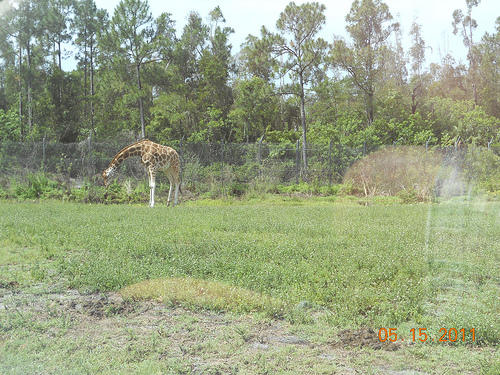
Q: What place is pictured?
A: It is a field.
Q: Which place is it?
A: It is a field.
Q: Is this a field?
A: Yes, it is a field.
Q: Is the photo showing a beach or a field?
A: It is showing a field.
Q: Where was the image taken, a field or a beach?
A: It was taken at a field.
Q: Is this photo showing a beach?
A: No, the picture is showing a field.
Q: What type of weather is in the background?
A: It is clear.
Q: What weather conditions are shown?
A: It is clear.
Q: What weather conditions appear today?
A: It is clear.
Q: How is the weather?
A: It is clear.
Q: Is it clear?
A: Yes, it is clear.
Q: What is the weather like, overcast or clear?
A: It is clear.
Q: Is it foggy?
A: No, it is clear.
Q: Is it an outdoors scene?
A: Yes, it is outdoors.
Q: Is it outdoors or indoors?
A: It is outdoors.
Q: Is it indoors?
A: No, it is outdoors.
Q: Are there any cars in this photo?
A: No, there are no cars.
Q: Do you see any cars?
A: No, there are no cars.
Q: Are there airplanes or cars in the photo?
A: No, there are no cars or airplanes.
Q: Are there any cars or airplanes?
A: No, there are no cars or airplanes.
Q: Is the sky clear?
A: Yes, the sky is clear.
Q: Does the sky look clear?
A: Yes, the sky is clear.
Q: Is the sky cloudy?
A: No, the sky is clear.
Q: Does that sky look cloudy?
A: No, the sky is clear.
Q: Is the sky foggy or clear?
A: The sky is clear.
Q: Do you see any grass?
A: Yes, there is grass.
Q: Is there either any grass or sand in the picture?
A: Yes, there is grass.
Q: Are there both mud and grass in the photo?
A: No, there is grass but no mud.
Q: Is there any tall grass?
A: Yes, there is tall grass.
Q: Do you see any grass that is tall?
A: Yes, there is grass that is tall.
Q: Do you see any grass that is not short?
A: Yes, there is tall grass.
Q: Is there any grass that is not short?
A: Yes, there is tall grass.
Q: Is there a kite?
A: No, there are no kites.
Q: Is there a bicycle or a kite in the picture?
A: No, there are no kites or bicycles.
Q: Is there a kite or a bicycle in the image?
A: No, there are no kites or bicycles.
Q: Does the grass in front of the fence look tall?
A: Yes, the grass is tall.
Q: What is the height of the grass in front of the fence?
A: The grass is tall.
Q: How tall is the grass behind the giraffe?
A: The grass is tall.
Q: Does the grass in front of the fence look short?
A: No, the grass is tall.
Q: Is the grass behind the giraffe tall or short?
A: The grass is tall.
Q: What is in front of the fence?
A: The grass is in front of the fence.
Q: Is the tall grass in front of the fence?
A: Yes, the grass is in front of the fence.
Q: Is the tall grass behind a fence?
A: No, the grass is in front of a fence.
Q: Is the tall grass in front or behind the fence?
A: The grass is in front of the fence.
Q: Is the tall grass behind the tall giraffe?
A: Yes, the grass is behind the giraffe.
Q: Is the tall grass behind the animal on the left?
A: Yes, the grass is behind the giraffe.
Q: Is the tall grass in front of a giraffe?
A: No, the grass is behind a giraffe.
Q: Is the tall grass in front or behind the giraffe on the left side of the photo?
A: The grass is behind the giraffe.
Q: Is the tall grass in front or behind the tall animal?
A: The grass is behind the giraffe.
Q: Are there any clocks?
A: No, there are no clocks.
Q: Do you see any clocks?
A: No, there are no clocks.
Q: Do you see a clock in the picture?
A: No, there are no clocks.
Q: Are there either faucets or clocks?
A: No, there are no clocks or faucets.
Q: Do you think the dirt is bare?
A: Yes, the dirt is bare.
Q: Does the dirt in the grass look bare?
A: Yes, the dirt is bare.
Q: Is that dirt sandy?
A: No, the dirt is bare.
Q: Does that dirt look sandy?
A: No, the dirt is bare.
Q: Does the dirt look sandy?
A: No, the dirt is bare.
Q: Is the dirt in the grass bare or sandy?
A: The dirt is bare.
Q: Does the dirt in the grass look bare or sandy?
A: The dirt is bare.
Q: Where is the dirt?
A: The dirt is in the grass.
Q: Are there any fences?
A: Yes, there is a fence.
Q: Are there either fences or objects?
A: Yes, there is a fence.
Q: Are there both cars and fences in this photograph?
A: No, there is a fence but no cars.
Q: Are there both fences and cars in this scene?
A: No, there is a fence but no cars.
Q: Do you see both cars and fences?
A: No, there is a fence but no cars.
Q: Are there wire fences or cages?
A: Yes, there is a wire fence.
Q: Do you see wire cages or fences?
A: Yes, there is a wire fence.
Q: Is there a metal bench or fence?
A: Yes, there is a metal fence.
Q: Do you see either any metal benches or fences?
A: Yes, there is a metal fence.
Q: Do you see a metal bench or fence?
A: Yes, there is a metal fence.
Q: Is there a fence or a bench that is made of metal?
A: Yes, the fence is made of metal.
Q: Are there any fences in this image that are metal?
A: Yes, there is a metal fence.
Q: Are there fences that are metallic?
A: Yes, there is a fence that is metallic.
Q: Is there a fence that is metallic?
A: Yes, there is a fence that is metallic.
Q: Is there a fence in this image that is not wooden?
A: Yes, there is a metallic fence.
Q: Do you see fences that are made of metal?
A: Yes, there is a fence that is made of metal.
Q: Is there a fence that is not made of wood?
A: Yes, there is a fence that is made of metal.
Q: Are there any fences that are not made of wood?
A: Yes, there is a fence that is made of metal.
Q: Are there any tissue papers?
A: No, there are no tissue papers.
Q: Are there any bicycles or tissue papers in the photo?
A: No, there are no tissue papers or bicycles.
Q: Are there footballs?
A: No, there are no footballs.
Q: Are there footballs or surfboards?
A: No, there are no footballs or surfboards.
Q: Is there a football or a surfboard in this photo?
A: No, there are no footballs or surfboards.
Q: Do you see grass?
A: Yes, there is grass.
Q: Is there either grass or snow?
A: Yes, there is grass.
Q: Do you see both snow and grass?
A: No, there is grass but no snow.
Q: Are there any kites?
A: No, there are no kites.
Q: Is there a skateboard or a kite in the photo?
A: No, there are no kites or skateboards.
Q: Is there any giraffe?
A: Yes, there is a giraffe.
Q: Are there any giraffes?
A: Yes, there is a giraffe.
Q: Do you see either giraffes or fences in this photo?
A: Yes, there is a giraffe.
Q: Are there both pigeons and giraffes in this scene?
A: No, there is a giraffe but no pigeons.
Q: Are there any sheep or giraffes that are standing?
A: Yes, the giraffe is standing.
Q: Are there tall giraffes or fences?
A: Yes, there is a tall giraffe.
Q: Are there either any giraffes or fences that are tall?
A: Yes, the giraffe is tall.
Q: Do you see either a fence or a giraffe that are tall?
A: Yes, the giraffe is tall.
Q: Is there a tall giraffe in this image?
A: Yes, there is a tall giraffe.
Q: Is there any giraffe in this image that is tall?
A: Yes, there is a giraffe that is tall.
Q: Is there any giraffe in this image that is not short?
A: Yes, there is a tall giraffe.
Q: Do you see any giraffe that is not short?
A: Yes, there is a tall giraffe.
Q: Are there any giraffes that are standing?
A: Yes, there is a giraffe that is standing.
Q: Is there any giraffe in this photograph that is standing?
A: Yes, there is a giraffe that is standing.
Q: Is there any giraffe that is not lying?
A: Yes, there is a giraffe that is standing.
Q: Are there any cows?
A: No, there are no cows.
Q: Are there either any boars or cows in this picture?
A: No, there are no cows or boars.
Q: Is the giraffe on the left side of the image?
A: Yes, the giraffe is on the left of the image.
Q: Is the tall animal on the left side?
A: Yes, the giraffe is on the left of the image.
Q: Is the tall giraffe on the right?
A: No, the giraffe is on the left of the image.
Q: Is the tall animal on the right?
A: No, the giraffe is on the left of the image.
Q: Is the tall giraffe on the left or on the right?
A: The giraffe is on the left of the image.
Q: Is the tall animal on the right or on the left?
A: The giraffe is on the left of the image.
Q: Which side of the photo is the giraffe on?
A: The giraffe is on the left of the image.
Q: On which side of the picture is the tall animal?
A: The giraffe is on the left of the image.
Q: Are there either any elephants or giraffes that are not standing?
A: No, there is a giraffe but it is standing.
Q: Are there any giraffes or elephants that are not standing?
A: No, there is a giraffe but it is standing.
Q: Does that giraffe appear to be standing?
A: Yes, the giraffe is standing.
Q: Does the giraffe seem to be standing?
A: Yes, the giraffe is standing.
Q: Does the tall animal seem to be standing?
A: Yes, the giraffe is standing.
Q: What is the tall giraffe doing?
A: The giraffe is standing.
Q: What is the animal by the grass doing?
A: The giraffe is standing.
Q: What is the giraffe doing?
A: The giraffe is standing.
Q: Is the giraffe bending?
A: No, the giraffe is standing.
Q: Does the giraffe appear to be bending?
A: No, the giraffe is standing.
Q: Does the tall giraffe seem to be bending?
A: No, the giraffe is standing.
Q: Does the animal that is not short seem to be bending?
A: No, the giraffe is standing.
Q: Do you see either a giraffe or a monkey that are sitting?
A: No, there is a giraffe but it is standing.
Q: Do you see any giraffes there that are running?
A: No, there is a giraffe but it is standing.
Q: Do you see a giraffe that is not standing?
A: No, there is a giraffe but it is standing.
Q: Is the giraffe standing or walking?
A: The giraffe is standing.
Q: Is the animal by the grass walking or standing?
A: The giraffe is standing.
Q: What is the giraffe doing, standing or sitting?
A: The giraffe is standing.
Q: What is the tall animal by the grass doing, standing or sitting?
A: The giraffe is standing.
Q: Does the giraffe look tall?
A: Yes, the giraffe is tall.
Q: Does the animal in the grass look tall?
A: Yes, the giraffe is tall.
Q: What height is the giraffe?
A: The giraffe is tall.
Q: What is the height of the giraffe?
A: The giraffe is tall.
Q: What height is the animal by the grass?
A: The giraffe is tall.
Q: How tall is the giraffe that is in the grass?
A: The giraffe is tall.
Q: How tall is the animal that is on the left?
A: The giraffe is tall.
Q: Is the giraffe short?
A: No, the giraffe is tall.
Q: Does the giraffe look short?
A: No, the giraffe is tall.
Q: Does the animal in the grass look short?
A: No, the giraffe is tall.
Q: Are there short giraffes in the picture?
A: No, there is a giraffe but it is tall.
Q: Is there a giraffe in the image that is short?
A: No, there is a giraffe but it is tall.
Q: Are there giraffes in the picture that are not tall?
A: No, there is a giraffe but it is tall.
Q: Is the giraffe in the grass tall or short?
A: The giraffe is tall.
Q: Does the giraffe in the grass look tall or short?
A: The giraffe is tall.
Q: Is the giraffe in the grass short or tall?
A: The giraffe is tall.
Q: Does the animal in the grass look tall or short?
A: The giraffe is tall.